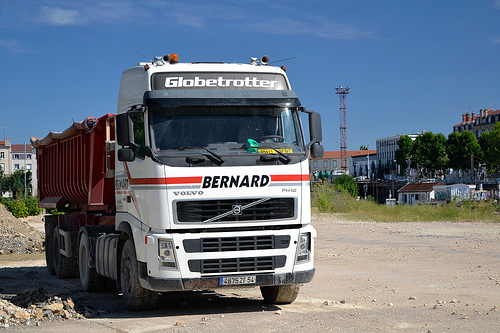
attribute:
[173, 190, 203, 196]
model name — silver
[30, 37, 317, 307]
truck — white, large, heavy duty, huge, powerful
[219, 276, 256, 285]
license plate — white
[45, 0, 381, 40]
clouds — small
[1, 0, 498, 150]
sky — blue, pretty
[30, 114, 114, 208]
bin — red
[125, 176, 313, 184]
stripe — red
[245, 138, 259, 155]
hat — green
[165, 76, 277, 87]
globetrotter — white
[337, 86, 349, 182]
tower — metal, tall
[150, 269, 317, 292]
bumper — silver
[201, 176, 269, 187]
bernard — black